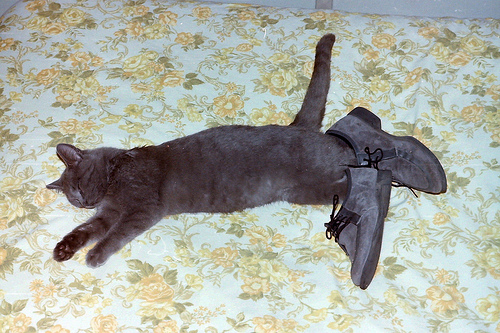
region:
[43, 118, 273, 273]
A gray cat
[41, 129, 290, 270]
A sleeping cat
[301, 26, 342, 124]
The tail of a cat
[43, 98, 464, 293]
A cat wearing shoes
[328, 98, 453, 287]
A pair of gray shoes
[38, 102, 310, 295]
A cat sleeping on a flowered comforter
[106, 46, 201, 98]
A yellow flower and leaves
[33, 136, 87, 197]
Two cat ears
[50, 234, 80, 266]
A cat's paw pads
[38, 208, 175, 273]
Two cat legs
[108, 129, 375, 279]
the cat is black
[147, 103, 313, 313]
the cat is black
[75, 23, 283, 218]
the cat is black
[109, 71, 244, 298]
the cat is black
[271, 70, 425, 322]
cat is wearing boots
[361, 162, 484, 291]
cat is wearing boots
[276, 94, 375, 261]
cat is wearing boots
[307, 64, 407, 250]
cat is wearing boots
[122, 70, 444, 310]
cat is wearing boots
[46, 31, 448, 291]
Grey cat wearing shoes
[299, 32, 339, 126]
Long grey cat tail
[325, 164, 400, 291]
Grey and black shoe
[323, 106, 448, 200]
Grey and black shoe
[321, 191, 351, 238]
Tied black shoe laces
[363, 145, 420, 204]
Untied black shoe laces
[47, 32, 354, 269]
Big grey sleeping cat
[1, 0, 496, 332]
Floral white table cloth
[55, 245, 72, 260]
Cat's pink paw pads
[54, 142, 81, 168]
Fury grey cat ear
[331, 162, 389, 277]
grey shoe on cat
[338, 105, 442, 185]
grey shoe on cat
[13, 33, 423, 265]
grey cat on bed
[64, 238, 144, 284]
front paw of cat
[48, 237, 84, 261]
front paw of cat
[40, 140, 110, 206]
head of grey cat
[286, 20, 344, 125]
tail of grey cat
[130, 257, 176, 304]
flowers in bunch on bed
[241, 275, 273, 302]
flowers in bunch on bed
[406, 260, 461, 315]
flowers in bunch on bed